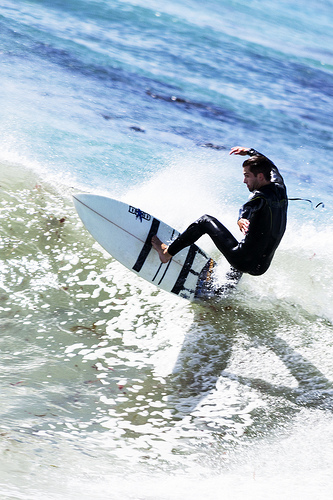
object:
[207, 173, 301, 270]
suit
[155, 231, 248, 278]
feet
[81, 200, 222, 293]
surfboard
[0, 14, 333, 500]
water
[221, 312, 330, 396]
shadows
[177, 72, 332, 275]
man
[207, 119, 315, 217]
arms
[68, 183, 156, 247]
board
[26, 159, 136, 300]
waves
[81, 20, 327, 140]
ocean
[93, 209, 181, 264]
strip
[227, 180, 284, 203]
beard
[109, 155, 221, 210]
foam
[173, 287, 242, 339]
cord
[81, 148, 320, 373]
surfer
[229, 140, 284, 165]
arm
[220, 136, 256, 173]
hand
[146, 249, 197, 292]
foot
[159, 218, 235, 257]
leg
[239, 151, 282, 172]
hair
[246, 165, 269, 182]
ear